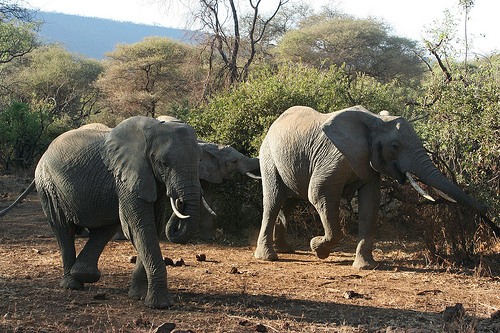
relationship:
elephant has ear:
[254, 105, 481, 270] [319, 109, 384, 182]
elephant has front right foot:
[254, 105, 481, 270] [306, 159, 349, 260]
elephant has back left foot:
[0, 115, 217, 308] [70, 225, 118, 283]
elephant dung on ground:
[128, 251, 239, 275] [0, 239, 499, 333]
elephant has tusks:
[0, 115, 217, 308] [169, 196, 217, 218]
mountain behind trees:
[0, 6, 233, 59] [0, 0, 499, 243]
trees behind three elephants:
[0, 0, 499, 243] [0, 104, 482, 310]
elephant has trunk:
[254, 105, 481, 270] [405, 142, 487, 216]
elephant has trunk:
[0, 115, 217, 308] [164, 171, 203, 243]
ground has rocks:
[0, 239, 499, 333] [152, 321, 194, 332]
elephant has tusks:
[254, 105, 481, 270] [405, 171, 458, 203]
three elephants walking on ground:
[0, 104, 482, 310] [0, 239, 499, 333]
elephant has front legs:
[254, 105, 481, 270] [307, 171, 381, 269]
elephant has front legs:
[0, 115, 217, 308] [119, 200, 172, 309]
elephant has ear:
[0, 115, 217, 308] [99, 115, 159, 202]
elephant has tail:
[0, 115, 217, 308] [0, 177, 36, 216]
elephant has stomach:
[254, 105, 481, 270] [275, 150, 310, 198]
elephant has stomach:
[0, 115, 217, 308] [56, 167, 118, 226]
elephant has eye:
[254, 105, 481, 270] [390, 140, 401, 151]